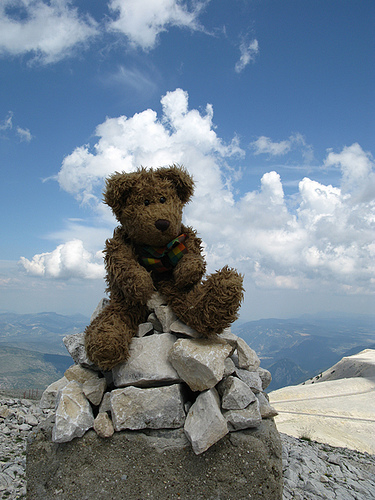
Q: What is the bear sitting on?
A: A pile of rocks.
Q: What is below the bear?
A: A valley of mountains.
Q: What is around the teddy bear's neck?
A: A bow.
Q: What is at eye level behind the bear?
A: White fluffy clouds.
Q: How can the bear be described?
A: A stuffed brown teddy bear.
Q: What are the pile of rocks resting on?
A: A large grey stone.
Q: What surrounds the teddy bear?
A: Gravel.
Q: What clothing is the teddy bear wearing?
A: A bow tie.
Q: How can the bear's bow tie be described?
A: A colorful plaid pattern.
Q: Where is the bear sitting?
A: On rocks.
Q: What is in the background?
A: Mountains and clouds.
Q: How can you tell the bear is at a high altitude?
A: Above mountains.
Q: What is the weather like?
A: Partially cloudy.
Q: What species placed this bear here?
A: A human.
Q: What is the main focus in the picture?
A: A teddy bear.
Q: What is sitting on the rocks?
A: A teddy bear.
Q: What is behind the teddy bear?
A: Clouds.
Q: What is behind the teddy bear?
A: The sky.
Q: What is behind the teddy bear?
A: Mountains.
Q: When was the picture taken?
A: During daytime.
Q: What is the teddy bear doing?
A: Sitting on rocks.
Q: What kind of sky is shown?
A: Cloudy.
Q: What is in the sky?
A: Clouds.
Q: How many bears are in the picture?
A: One.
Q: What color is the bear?
A: Brown.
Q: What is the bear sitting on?
A: Rocks.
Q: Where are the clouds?
A: In the sky.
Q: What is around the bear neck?
A: A tie.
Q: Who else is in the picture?
A: No one.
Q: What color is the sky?
A: Blue.